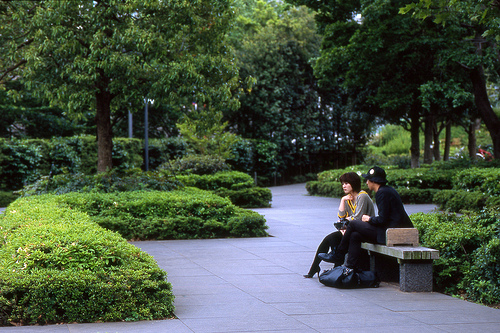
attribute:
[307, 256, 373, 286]
black bag — large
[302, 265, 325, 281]
high-heeled shoe — dark-colored, black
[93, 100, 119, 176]
tree trunk — large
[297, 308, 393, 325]
cement block — large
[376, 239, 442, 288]
park bench — concrete, stone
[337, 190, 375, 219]
gray sweater — beige, yellow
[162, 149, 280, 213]
green bush — trimmed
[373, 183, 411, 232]
shirt — black